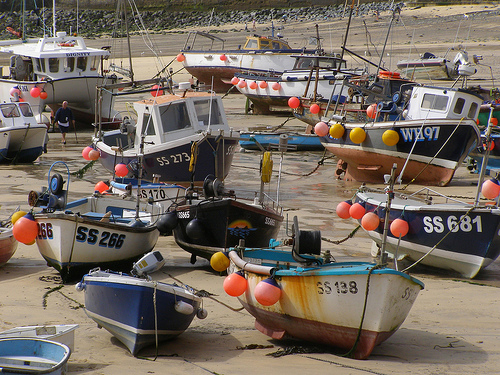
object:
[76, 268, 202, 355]
boat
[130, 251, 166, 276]
motor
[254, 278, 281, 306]
buoy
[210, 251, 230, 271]
buoy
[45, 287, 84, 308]
line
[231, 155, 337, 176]
rope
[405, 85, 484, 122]
cabin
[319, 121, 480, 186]
boat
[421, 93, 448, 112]
window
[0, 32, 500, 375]
boats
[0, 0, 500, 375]
beach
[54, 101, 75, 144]
person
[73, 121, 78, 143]
stick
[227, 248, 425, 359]
boat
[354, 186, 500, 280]
boat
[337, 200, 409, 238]
balloons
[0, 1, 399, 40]
grass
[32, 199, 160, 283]
boat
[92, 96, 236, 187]
boat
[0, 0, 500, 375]
ground